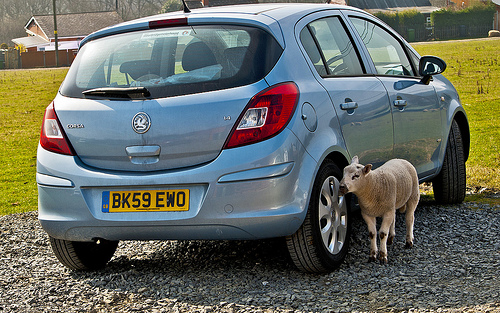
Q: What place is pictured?
A: It is a field.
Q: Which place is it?
A: It is a field.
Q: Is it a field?
A: Yes, it is a field.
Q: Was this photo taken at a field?
A: Yes, it was taken in a field.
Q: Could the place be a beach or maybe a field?
A: It is a field.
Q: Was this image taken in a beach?
A: No, the picture was taken in a field.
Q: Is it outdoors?
A: Yes, it is outdoors.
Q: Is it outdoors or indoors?
A: It is outdoors.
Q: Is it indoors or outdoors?
A: It is outdoors.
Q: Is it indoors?
A: No, it is outdoors.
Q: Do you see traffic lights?
A: No, there are no traffic lights.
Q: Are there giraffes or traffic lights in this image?
A: No, there are no traffic lights or giraffes.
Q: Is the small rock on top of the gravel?
A: Yes, the rock is on top of the gravel.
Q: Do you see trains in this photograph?
A: No, there are no trains.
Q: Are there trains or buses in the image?
A: No, there are no trains or buses.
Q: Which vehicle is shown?
A: The vehicle is a car.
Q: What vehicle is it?
A: The vehicle is a car.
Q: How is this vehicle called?
A: This is a car.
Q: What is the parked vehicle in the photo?
A: The vehicle is a car.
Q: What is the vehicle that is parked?
A: The vehicle is a car.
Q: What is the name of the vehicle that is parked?
A: The vehicle is a car.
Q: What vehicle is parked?
A: The vehicle is a car.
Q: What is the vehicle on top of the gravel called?
A: The vehicle is a car.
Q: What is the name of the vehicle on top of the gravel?
A: The vehicle is a car.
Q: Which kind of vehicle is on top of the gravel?
A: The vehicle is a car.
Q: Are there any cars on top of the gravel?
A: Yes, there is a car on top of the gravel.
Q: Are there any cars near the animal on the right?
A: Yes, there is a car near the lamb.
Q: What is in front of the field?
A: The car is in front of the field.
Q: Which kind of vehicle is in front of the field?
A: The vehicle is a car.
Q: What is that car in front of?
A: The car is in front of the field.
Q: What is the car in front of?
A: The car is in front of the field.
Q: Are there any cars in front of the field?
A: Yes, there is a car in front of the field.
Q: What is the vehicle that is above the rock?
A: The vehicle is a car.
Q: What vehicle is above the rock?
A: The vehicle is a car.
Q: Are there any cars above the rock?
A: Yes, there is a car above the rock.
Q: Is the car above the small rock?
A: Yes, the car is above the rock.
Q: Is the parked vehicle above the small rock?
A: Yes, the car is above the rock.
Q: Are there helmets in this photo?
A: No, there are no helmets.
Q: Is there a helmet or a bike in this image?
A: No, there are no helmets or bikes.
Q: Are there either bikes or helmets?
A: No, there are no helmets or bikes.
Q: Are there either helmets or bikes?
A: No, there are no helmets or bikes.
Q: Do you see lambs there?
A: Yes, there is a lamb.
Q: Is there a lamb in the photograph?
A: Yes, there is a lamb.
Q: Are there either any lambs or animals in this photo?
A: Yes, there is a lamb.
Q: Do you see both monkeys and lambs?
A: No, there is a lamb but no monkeys.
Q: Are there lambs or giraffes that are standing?
A: Yes, the lamb is standing.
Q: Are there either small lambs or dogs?
A: Yes, there is a small lamb.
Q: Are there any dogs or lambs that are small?
A: Yes, the lamb is small.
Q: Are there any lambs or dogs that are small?
A: Yes, the lamb is small.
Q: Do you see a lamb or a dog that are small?
A: Yes, the lamb is small.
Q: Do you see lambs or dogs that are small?
A: Yes, the lamb is small.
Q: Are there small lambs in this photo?
A: Yes, there is a small lamb.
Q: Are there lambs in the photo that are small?
A: Yes, there is a lamb that is small.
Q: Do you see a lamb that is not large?
A: Yes, there is a small lamb.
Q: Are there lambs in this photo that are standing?
A: Yes, there is a lamb that is standing.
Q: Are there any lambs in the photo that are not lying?
A: Yes, there is a lamb that is standing.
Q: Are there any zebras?
A: No, there are no zebras.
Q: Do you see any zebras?
A: No, there are no zebras.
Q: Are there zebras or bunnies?
A: No, there are no zebras or bunnies.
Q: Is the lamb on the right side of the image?
A: Yes, the lamb is on the right of the image.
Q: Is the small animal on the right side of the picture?
A: Yes, the lamb is on the right of the image.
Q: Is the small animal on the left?
A: No, the lamb is on the right of the image.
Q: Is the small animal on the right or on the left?
A: The lamb is on the right of the image.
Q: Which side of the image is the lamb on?
A: The lamb is on the right of the image.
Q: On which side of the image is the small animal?
A: The lamb is on the right of the image.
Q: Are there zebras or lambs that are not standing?
A: No, there is a lamb but it is standing.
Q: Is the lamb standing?
A: Yes, the lamb is standing.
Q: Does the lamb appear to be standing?
A: Yes, the lamb is standing.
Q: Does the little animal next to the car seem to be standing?
A: Yes, the lamb is standing.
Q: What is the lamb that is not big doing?
A: The lamb is standing.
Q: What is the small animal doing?
A: The lamb is standing.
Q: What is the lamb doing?
A: The lamb is standing.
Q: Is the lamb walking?
A: No, the lamb is standing.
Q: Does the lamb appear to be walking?
A: No, the lamb is standing.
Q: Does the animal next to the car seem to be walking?
A: No, the lamb is standing.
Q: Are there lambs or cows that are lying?
A: No, there is a lamb but it is standing.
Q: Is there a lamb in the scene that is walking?
A: No, there is a lamb but it is standing.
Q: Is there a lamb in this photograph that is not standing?
A: No, there is a lamb but it is standing.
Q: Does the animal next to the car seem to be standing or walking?
A: The lamb is standing.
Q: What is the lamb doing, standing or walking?
A: The lamb is standing.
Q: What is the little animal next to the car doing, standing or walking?
A: The lamb is standing.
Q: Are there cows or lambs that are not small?
A: No, there is a lamb but it is small.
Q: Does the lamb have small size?
A: Yes, the lamb is small.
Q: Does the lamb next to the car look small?
A: Yes, the lamb is small.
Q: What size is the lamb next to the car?
A: The lamb is small.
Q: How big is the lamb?
A: The lamb is small.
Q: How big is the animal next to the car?
A: The lamb is small.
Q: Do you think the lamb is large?
A: No, the lamb is small.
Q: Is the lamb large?
A: No, the lamb is small.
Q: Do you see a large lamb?
A: No, there is a lamb but it is small.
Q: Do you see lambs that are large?
A: No, there is a lamb but it is small.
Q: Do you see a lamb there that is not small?
A: No, there is a lamb but it is small.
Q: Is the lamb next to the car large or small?
A: The lamb is small.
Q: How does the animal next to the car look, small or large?
A: The lamb is small.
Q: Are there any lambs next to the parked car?
A: Yes, there is a lamb next to the car.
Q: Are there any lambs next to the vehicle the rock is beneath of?
A: Yes, there is a lamb next to the car.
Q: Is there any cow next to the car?
A: No, there is a lamb next to the car.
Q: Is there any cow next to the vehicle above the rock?
A: No, there is a lamb next to the car.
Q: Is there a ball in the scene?
A: No, there are no balls.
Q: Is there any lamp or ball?
A: No, there are no balls or lamps.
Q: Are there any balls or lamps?
A: No, there are no balls or lamps.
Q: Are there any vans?
A: No, there are no vans.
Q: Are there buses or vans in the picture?
A: No, there are no vans or buses.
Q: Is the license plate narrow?
A: Yes, the license plate is narrow.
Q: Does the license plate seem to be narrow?
A: Yes, the license plate is narrow.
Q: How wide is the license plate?
A: The license plate is narrow.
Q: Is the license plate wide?
A: No, the license plate is narrow.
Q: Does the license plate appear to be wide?
A: No, the license plate is narrow.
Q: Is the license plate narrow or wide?
A: The license plate is narrow.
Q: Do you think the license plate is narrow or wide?
A: The license plate is narrow.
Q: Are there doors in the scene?
A: Yes, there is a door.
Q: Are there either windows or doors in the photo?
A: Yes, there is a door.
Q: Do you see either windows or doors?
A: Yes, there is a door.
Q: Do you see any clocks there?
A: No, there are no clocks.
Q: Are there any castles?
A: No, there are no castles.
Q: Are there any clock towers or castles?
A: No, there are no castles or clock towers.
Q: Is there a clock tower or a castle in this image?
A: No, there are no castles or clock towers.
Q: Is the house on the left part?
A: Yes, the house is on the left of the image.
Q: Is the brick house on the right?
A: No, the house is on the left of the image.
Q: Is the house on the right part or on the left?
A: The house is on the left of the image.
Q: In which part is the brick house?
A: The house is on the left of the image.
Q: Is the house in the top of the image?
A: Yes, the house is in the top of the image.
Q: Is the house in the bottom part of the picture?
A: No, the house is in the top of the image.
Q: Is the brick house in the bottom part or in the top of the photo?
A: The house is in the top of the image.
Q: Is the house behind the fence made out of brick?
A: Yes, the house is made of brick.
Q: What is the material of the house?
A: The house is made of brick.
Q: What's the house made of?
A: The house is made of brick.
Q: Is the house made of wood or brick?
A: The house is made of brick.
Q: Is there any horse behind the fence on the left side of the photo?
A: No, there is a house behind the fence.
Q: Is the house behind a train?
A: No, the house is behind the fence.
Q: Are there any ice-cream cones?
A: No, there are no ice-cream cones.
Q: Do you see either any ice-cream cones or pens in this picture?
A: No, there are no ice-cream cones or pens.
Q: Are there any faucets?
A: No, there are no faucets.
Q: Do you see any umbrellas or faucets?
A: No, there are no faucets or umbrellas.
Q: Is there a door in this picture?
A: Yes, there is a door.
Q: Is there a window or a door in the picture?
A: Yes, there is a door.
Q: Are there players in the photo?
A: No, there are no players.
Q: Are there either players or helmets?
A: No, there are no players or helmets.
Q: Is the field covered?
A: Yes, the field is covered.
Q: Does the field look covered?
A: Yes, the field is covered.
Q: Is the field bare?
A: No, the field is covered.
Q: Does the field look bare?
A: No, the field is covered.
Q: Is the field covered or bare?
A: The field is covered.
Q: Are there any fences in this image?
A: Yes, there is a fence.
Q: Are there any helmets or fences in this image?
A: Yes, there is a fence.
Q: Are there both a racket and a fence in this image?
A: No, there is a fence but no rackets.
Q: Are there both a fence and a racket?
A: No, there is a fence but no rackets.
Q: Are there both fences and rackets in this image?
A: No, there is a fence but no rackets.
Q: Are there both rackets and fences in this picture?
A: No, there is a fence but no rackets.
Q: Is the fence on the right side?
A: No, the fence is on the left of the image.